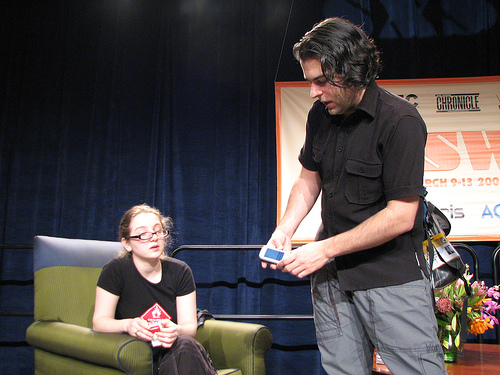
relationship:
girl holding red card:
[90, 200, 234, 371] [139, 300, 170, 336]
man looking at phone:
[258, 13, 449, 375] [260, 238, 292, 264]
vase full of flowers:
[433, 261, 495, 367] [423, 269, 498, 349]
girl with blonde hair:
[90, 200, 234, 371] [96, 192, 186, 261]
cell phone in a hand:
[258, 246, 291, 265] [255, 234, 334, 281]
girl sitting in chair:
[90, 200, 223, 375] [20, 225, 277, 373]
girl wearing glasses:
[90, 200, 234, 371] [122, 227, 170, 241]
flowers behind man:
[425, 255, 499, 370] [275, 25, 470, 374]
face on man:
[285, 28, 377, 94] [298, 35, 413, 321]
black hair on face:
[291, 9, 372, 74] [285, 28, 377, 94]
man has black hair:
[298, 35, 413, 321] [291, 9, 372, 74]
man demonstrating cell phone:
[258, 13, 449, 375] [256, 246, 300, 269]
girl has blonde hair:
[90, 200, 223, 375] [116, 203, 179, 261]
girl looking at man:
[90, 200, 223, 375] [258, 13, 449, 375]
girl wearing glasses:
[90, 200, 223, 375] [122, 225, 171, 241]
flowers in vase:
[432, 263, 500, 364] [424, 302, 471, 365]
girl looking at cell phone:
[90, 200, 223, 375] [259, 241, 289, 268]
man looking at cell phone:
[258, 13, 449, 375] [259, 241, 289, 268]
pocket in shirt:
[343, 154, 381, 213] [295, 78, 425, 288]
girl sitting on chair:
[90, 200, 223, 375] [25, 234, 275, 375]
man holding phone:
[258, 13, 449, 375] [253, 242, 291, 267]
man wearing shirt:
[258, 13, 449, 375] [295, 78, 425, 288]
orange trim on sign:
[270, 74, 499, 243] [262, 74, 497, 254]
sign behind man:
[262, 74, 497, 254] [258, 13, 449, 375]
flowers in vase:
[432, 263, 500, 364] [439, 324, 460, 364]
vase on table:
[439, 324, 460, 364] [355, 306, 498, 372]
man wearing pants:
[258, 13, 449, 375] [301, 268, 438, 373]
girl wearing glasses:
[90, 200, 223, 375] [133, 227, 168, 242]